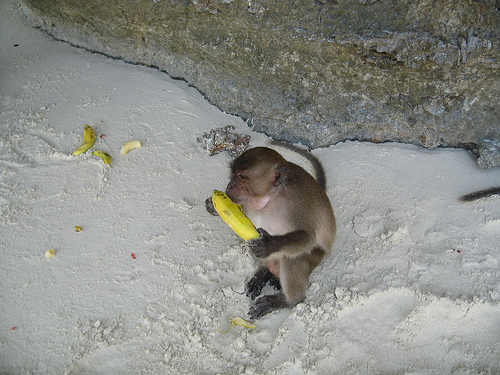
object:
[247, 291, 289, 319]
foot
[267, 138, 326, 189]
tail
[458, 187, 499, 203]
tail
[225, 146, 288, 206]
head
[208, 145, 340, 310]
monkey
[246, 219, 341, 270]
arm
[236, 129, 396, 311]
monkey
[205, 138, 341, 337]
monkey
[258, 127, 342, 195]
tail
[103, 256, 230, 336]
footprints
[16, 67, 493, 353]
snow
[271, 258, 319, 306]
thigh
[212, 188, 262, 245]
banana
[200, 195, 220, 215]
hand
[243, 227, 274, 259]
hand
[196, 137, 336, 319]
monkey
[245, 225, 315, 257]
arm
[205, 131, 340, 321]
monkey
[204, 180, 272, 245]
banana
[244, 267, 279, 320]
claws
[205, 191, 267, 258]
banana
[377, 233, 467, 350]
beach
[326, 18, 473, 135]
rock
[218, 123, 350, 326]
monkey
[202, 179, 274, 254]
banana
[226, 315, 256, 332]
banana skin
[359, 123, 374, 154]
rock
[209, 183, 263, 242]
banana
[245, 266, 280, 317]
feet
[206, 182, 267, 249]
banana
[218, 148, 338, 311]
monkey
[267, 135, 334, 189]
tail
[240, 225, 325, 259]
hand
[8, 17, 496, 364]
snow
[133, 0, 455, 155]
rock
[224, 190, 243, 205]
mouth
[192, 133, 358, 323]
monkey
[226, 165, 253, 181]
eyes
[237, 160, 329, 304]
monkey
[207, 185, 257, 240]
banana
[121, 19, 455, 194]
wall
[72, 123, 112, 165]
peel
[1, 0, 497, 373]
ground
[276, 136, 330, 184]
tail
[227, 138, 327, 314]
monkey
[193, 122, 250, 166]
object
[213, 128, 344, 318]
monkey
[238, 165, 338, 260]
body